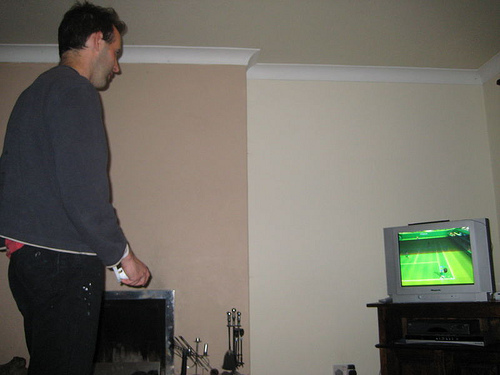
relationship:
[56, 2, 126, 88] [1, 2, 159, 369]
head on man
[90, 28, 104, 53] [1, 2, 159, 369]
ear on man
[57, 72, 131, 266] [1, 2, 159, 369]
arm on man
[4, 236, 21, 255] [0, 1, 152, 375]
undershirt on hand man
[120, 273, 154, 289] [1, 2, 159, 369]
fingers of a man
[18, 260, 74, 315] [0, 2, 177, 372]
pockets of a man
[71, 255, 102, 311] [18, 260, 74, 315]
pockets of a pockets